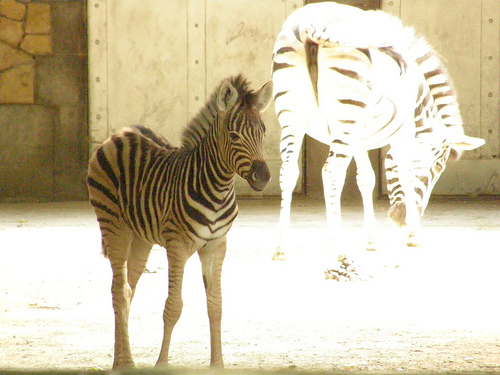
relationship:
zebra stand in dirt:
[86, 71, 275, 373] [279, 260, 357, 342]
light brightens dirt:
[276, 229, 413, 331] [279, 260, 357, 342]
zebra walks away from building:
[86, 71, 275, 373] [3, 12, 261, 107]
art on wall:
[0, 4, 66, 111] [3, 4, 87, 149]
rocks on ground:
[325, 248, 365, 289] [0, 196, 499, 374]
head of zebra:
[218, 80, 277, 197] [86, 71, 275, 373]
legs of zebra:
[92, 229, 239, 362] [86, 71, 275, 373]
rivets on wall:
[83, 0, 109, 135] [200, 8, 264, 77]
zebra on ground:
[86, 71, 275, 373] [65, 287, 468, 357]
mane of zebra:
[180, 97, 214, 151] [86, 71, 275, 373]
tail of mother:
[288, 21, 412, 61] [262, 3, 493, 234]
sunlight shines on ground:
[260, 227, 321, 347] [65, 287, 468, 357]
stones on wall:
[0, 35, 35, 100] [3, 4, 87, 149]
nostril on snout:
[252, 171, 260, 178] [248, 159, 272, 191]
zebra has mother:
[44, 17, 311, 373] [262, 3, 493, 234]